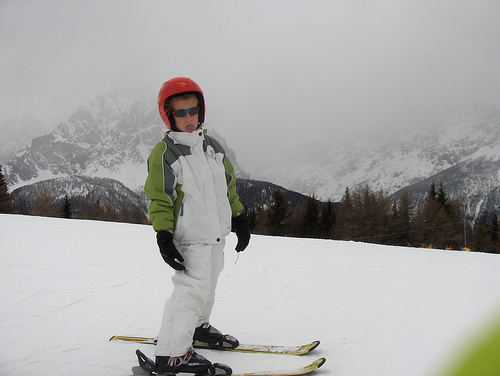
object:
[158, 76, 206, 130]
helmet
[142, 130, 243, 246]
jacket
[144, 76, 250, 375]
boy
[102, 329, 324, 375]
skis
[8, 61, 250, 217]
mountains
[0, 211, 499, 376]
snow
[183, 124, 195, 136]
tongue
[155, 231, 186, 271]
gloves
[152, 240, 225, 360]
pants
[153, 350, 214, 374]
ski shoes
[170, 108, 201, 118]
glasses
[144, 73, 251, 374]
girl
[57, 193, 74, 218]
trees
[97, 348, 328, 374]
ski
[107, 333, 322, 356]
ski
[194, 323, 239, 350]
ski boot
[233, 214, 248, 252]
glove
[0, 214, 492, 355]
ground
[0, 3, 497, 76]
sky